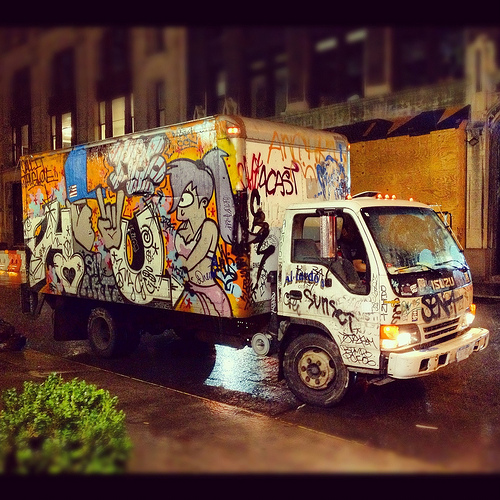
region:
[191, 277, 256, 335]
Graffiti on a truck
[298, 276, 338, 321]
Graffiti on a truck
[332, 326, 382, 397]
Graffiti on a truck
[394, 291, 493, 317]
Graffiti on a truck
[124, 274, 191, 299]
Graffiti on a truck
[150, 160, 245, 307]
Graffiti on a truck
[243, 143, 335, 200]
Graffiti on a truck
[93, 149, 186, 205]
Graffiti on a truck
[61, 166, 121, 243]
Graffiti on a truck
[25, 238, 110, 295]
Graffiti on a truck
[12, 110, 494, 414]
grafitti on the truck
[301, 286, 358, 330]
sunset on the truck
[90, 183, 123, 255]
hand on the truck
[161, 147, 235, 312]
girl on the truck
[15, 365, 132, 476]
bush on the sidewalk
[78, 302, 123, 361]
black tires on truck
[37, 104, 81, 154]
window on the building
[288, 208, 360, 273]
window on the truck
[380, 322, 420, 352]
lights on the truck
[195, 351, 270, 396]
wet pavement under truck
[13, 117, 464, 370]
white box truck covered graffiti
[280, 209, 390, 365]
passenger door of truck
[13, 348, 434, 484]
sidewalk beside box truck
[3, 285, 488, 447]
street box truck is parked on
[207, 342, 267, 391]
reflection of light on street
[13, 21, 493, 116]
buildings behind box truck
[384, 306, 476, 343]
headlights of white truck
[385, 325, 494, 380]
white front bumper of truck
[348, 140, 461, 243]
boarded up windows of storefront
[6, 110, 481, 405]
The truck has grafiti on it.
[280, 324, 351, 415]
The tire is black.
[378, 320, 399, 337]
The light is orange.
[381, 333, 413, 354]
The light is white.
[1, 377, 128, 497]
The bush is leafy.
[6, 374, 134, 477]
The tree is green.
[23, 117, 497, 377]
The truck is colorful.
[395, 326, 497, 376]
The bumper is white.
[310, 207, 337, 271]
The mirror is silver.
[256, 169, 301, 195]
The writing is black.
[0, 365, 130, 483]
bush in foreground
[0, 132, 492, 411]
truck with graffiti painted on it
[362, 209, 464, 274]
front window is dirty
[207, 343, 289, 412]
pavement looks wet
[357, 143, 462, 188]
yellow wall in background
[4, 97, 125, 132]
building with rows of windows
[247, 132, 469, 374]
the truck was originally white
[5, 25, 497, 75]
edges of scene have been blurred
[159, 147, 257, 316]
cartoon character painted on truck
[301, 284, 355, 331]
the word sunset is written on the truck